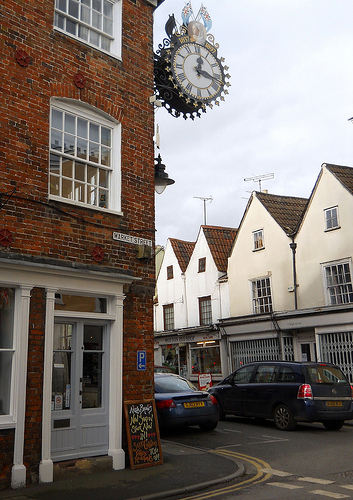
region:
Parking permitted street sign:
[132, 347, 150, 374]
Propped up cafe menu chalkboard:
[121, 397, 168, 469]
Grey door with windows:
[53, 314, 113, 460]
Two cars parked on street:
[153, 358, 351, 436]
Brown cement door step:
[43, 452, 120, 476]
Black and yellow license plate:
[180, 399, 208, 409]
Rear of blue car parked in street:
[152, 368, 225, 434]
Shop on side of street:
[154, 323, 230, 384]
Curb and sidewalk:
[154, 436, 244, 488]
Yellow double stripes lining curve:
[210, 439, 274, 496]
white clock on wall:
[155, 29, 220, 122]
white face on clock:
[166, 51, 230, 95]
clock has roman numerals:
[159, 47, 232, 97]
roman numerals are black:
[171, 48, 230, 97]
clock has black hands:
[171, 53, 214, 95]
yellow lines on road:
[197, 408, 297, 490]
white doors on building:
[46, 306, 122, 463]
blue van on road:
[212, 350, 344, 438]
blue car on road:
[138, 356, 247, 426]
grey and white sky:
[252, 77, 322, 150]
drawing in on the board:
[127, 402, 163, 459]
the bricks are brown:
[127, 307, 166, 394]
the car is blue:
[214, 352, 349, 432]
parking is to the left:
[133, 349, 147, 372]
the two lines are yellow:
[238, 453, 277, 487]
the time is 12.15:
[170, 39, 233, 102]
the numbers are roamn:
[174, 40, 221, 96]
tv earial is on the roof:
[193, 183, 215, 219]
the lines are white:
[261, 461, 333, 496]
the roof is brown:
[209, 227, 224, 261]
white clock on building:
[134, 7, 250, 135]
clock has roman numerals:
[162, 30, 221, 121]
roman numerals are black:
[159, 40, 213, 120]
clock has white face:
[142, 39, 212, 118]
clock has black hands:
[171, 38, 229, 104]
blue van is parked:
[197, 356, 347, 445]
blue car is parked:
[136, 361, 218, 435]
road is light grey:
[207, 430, 346, 476]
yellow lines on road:
[243, 432, 338, 497]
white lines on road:
[191, 401, 257, 452]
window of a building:
[76, 323, 104, 345]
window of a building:
[49, 318, 81, 347]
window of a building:
[51, 347, 77, 371]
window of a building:
[56, 371, 88, 394]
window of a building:
[39, 111, 67, 131]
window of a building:
[41, 145, 67, 168]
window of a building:
[90, 161, 110, 185]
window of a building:
[192, 285, 219, 327]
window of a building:
[156, 289, 178, 331]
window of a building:
[243, 263, 284, 317]